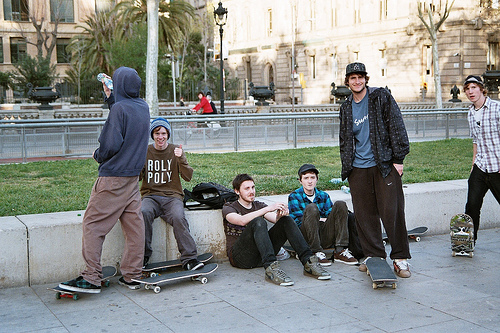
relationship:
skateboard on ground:
[360, 250, 394, 297] [0, 225, 499, 332]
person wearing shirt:
[188, 88, 218, 121] [196, 98, 215, 114]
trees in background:
[77, 13, 202, 96] [6, 4, 486, 114]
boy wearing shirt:
[149, 112, 207, 267] [147, 146, 193, 196]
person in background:
[188, 88, 218, 121] [6, 4, 486, 114]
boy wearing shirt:
[446, 75, 500, 245] [463, 101, 499, 176]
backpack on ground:
[184, 171, 234, 205] [1, 130, 500, 217]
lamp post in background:
[210, 1, 234, 132] [6, 4, 486, 114]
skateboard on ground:
[41, 263, 120, 302] [0, 225, 499, 332]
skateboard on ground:
[133, 260, 220, 292] [0, 225, 499, 332]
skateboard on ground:
[138, 246, 214, 272] [0, 225, 499, 332]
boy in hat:
[323, 61, 425, 285] [342, 63, 366, 77]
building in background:
[179, 1, 496, 109] [6, 4, 486, 114]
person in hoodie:
[66, 53, 161, 287] [92, 67, 151, 178]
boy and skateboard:
[138, 118, 204, 272] [133, 260, 220, 292]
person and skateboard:
[323, 61, 425, 285] [360, 250, 394, 297]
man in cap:
[282, 163, 360, 268] [296, 164, 327, 175]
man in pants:
[446, 75, 500, 245] [466, 165, 500, 258]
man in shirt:
[149, 112, 207, 267] [147, 146, 193, 196]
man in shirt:
[446, 75, 500, 245] [463, 101, 499, 176]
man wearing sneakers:
[66, 53, 161, 287] [49, 269, 145, 301]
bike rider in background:
[186, 89, 222, 143] [6, 4, 486, 114]